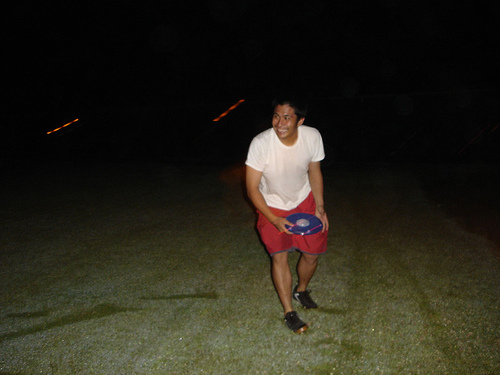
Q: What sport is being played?
A: Frisbee.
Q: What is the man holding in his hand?
A: Frisbee disc.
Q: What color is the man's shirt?
A: White.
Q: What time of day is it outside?
A: Night time.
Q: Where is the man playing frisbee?
A: Street.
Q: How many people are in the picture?
A: One.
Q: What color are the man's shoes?
A: Black.